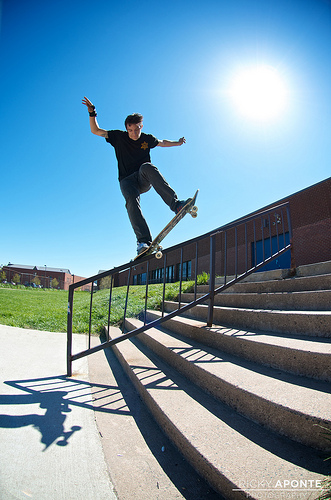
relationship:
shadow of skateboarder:
[0, 388, 82, 448] [76, 91, 202, 254]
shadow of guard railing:
[132, 362, 189, 403] [68, 275, 242, 357]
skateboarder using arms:
[76, 91, 202, 254] [76, 93, 191, 149]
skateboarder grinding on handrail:
[76, 91, 202, 254] [73, 275, 123, 288]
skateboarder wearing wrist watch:
[76, 91, 202, 254] [87, 112, 97, 118]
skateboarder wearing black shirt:
[76, 91, 202, 254] [109, 137, 159, 169]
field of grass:
[2, 292, 71, 328] [31, 290, 57, 304]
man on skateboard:
[76, 91, 202, 254] [149, 205, 194, 263]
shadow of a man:
[0, 388, 82, 448] [76, 91, 202, 254]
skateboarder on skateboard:
[76, 91, 202, 254] [149, 205, 194, 263]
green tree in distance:
[22, 303, 45, 311] [3, 235, 66, 318]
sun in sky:
[216, 82, 296, 138] [64, 15, 156, 80]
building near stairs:
[216, 208, 319, 274] [233, 310, 309, 447]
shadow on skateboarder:
[0, 388, 82, 448] [76, 91, 202, 254]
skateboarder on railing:
[76, 91, 202, 254] [68, 275, 242, 357]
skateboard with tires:
[149, 205, 194, 263] [187, 207, 199, 218]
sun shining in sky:
[216, 82, 296, 138] [64, 15, 156, 80]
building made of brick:
[216, 208, 319, 274] [300, 205, 327, 224]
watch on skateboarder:
[87, 112, 97, 118] [76, 91, 202, 254]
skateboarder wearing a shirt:
[76, 91, 202, 254] [109, 137, 159, 169]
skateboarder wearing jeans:
[76, 91, 202, 254] [116, 164, 182, 207]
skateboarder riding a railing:
[76, 91, 202, 254] [68, 275, 242, 357]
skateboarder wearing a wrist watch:
[76, 91, 202, 254] [87, 112, 97, 118]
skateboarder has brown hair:
[76, 91, 202, 254] [127, 114, 143, 122]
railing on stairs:
[68, 275, 242, 357] [233, 310, 309, 447]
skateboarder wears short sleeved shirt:
[76, 91, 202, 254] [109, 137, 159, 169]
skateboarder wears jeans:
[76, 91, 202, 254] [116, 164, 182, 207]